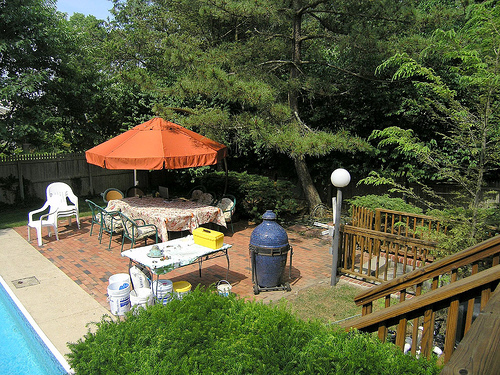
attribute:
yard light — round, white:
[330, 166, 352, 188]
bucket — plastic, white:
[126, 263, 152, 289]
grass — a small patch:
[288, 279, 369, 323]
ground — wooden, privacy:
[420, 149, 460, 191]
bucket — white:
[102, 280, 134, 315]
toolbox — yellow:
[184, 212, 227, 255]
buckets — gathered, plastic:
[106, 267, 193, 314]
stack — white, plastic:
[46, 179, 84, 239]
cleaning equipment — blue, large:
[247, 210, 290, 292]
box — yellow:
[190, 225, 225, 251]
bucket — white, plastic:
[105, 279, 134, 317]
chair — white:
[26, 195, 59, 245]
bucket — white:
[199, 276, 247, 303]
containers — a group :
[101, 270, 159, 317]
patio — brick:
[13, 202, 332, 320]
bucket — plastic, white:
[92, 272, 151, 327]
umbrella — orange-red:
[86, 116, 228, 170]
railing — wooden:
[334, 233, 498, 373]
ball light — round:
[327, 164, 354, 194]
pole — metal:
[328, 190, 345, 285]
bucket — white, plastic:
[103, 272, 133, 289]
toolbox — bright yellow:
[186, 227, 223, 250]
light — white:
[328, 167, 353, 185]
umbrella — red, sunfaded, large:
[79, 115, 226, 196]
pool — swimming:
[0, 277, 450, 369]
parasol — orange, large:
[81, 111, 226, 175]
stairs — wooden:
[336, 231, 498, 369]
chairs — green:
[84, 191, 172, 251]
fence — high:
[8, 138, 188, 199]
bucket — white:
[129, 286, 152, 311]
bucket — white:
[110, 281, 132, 319]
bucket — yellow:
[174, 279, 191, 294]